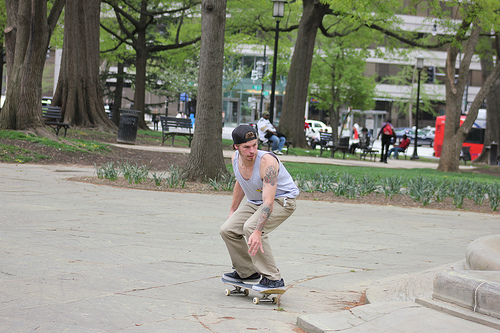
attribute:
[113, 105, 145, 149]
trash can — black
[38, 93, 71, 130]
bench — black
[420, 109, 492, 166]
bus — red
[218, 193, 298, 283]
pants — tan, long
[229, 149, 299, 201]
top — gray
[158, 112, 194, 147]
bench — black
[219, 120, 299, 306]
man — young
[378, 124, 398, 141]
backpack — red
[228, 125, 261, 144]
hat — black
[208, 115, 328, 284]
man — young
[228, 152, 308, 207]
top — grey